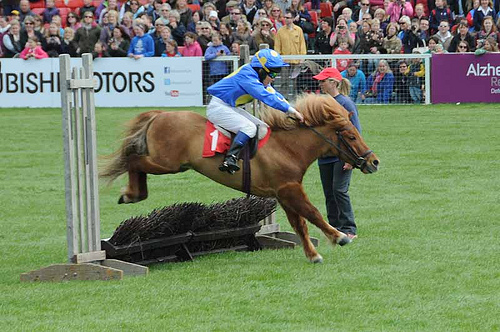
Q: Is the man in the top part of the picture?
A: Yes, the man is in the top of the image.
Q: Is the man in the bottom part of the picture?
A: No, the man is in the top of the image.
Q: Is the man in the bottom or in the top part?
A: The man is in the top of the image.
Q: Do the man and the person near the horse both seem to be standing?
A: Yes, both the man and the person are standing.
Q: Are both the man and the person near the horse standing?
A: Yes, both the man and the person are standing.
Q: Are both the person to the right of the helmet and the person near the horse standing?
A: Yes, both the man and the person are standing.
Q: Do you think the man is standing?
A: Yes, the man is standing.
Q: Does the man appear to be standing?
A: Yes, the man is standing.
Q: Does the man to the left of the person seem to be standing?
A: Yes, the man is standing.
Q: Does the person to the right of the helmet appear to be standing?
A: Yes, the man is standing.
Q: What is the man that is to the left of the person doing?
A: The man is standing.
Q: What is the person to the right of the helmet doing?
A: The man is standing.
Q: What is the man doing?
A: The man is standing.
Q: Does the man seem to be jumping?
A: No, the man is standing.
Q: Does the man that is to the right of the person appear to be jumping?
A: No, the man is standing.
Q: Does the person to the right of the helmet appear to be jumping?
A: No, the man is standing.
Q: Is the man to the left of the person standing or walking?
A: The man is standing.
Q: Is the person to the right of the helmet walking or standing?
A: The man is standing.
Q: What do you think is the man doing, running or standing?
A: The man is standing.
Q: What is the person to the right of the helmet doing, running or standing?
A: The man is standing.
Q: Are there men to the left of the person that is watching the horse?
A: Yes, there is a man to the left of the person.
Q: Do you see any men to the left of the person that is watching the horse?
A: Yes, there is a man to the left of the person.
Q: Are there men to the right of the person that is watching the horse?
A: No, the man is to the left of the person.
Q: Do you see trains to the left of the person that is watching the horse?
A: No, there is a man to the left of the person.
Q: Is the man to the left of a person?
A: Yes, the man is to the left of a person.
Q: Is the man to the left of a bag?
A: No, the man is to the left of a person.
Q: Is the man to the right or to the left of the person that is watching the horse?
A: The man is to the left of the person.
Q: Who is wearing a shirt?
A: The man is wearing a shirt.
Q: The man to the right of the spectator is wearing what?
A: The man is wearing a shirt.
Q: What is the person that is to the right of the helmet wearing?
A: The man is wearing a shirt.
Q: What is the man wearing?
A: The man is wearing a shirt.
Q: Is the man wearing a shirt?
A: Yes, the man is wearing a shirt.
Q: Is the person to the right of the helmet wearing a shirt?
A: Yes, the man is wearing a shirt.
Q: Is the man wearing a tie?
A: No, the man is wearing a shirt.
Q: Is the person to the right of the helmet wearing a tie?
A: No, the man is wearing a shirt.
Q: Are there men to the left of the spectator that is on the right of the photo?
A: Yes, there is a man to the left of the spectator.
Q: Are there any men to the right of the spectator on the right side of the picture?
A: No, the man is to the left of the spectator.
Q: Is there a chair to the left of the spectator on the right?
A: No, there is a man to the left of the spectator.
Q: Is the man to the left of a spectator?
A: Yes, the man is to the left of a spectator.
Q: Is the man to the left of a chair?
A: No, the man is to the left of a spectator.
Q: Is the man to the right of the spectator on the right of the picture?
A: No, the man is to the left of the spectator.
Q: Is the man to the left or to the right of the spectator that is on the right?
A: The man is to the left of the spectator.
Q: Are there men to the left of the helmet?
A: No, the man is to the right of the helmet.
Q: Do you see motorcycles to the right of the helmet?
A: No, there is a man to the right of the helmet.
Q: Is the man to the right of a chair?
A: No, the man is to the right of the helmet.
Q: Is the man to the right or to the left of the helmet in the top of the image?
A: The man is to the right of the helmet.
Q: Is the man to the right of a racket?
A: No, the man is to the right of a person.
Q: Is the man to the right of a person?
A: Yes, the man is to the right of a person.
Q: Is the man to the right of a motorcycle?
A: No, the man is to the right of a person.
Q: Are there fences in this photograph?
A: Yes, there is a fence.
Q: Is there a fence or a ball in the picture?
A: Yes, there is a fence.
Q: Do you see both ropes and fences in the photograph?
A: No, there is a fence but no ropes.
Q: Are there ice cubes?
A: No, there are no ice cubes.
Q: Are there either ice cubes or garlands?
A: No, there are no ice cubes or garlands.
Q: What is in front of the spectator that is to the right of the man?
A: The fence is in front of the spectator.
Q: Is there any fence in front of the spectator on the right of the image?
A: Yes, there is a fence in front of the spectator.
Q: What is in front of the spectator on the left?
A: The fence is in front of the spectator.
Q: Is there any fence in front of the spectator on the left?
A: Yes, there is a fence in front of the spectator.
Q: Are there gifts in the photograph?
A: No, there are no gifts.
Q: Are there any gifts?
A: No, there are no gifts.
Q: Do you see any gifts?
A: No, there are no gifts.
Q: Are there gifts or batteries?
A: No, there are no gifts or batteries.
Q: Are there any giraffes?
A: No, there are no giraffes.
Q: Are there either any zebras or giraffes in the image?
A: No, there are no giraffes or zebras.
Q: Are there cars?
A: No, there are no cars.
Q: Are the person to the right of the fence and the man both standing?
A: Yes, both the person and the man are standing.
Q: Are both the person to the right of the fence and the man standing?
A: Yes, both the person and the man are standing.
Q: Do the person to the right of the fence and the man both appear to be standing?
A: Yes, both the person and the man are standing.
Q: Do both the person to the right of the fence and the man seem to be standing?
A: Yes, both the person and the man are standing.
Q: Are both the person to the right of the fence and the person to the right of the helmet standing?
A: Yes, both the person and the man are standing.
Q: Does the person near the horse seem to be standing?
A: Yes, the person is standing.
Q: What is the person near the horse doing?
A: The person is standing.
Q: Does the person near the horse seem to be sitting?
A: No, the person is standing.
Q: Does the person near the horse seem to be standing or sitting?
A: The person is standing.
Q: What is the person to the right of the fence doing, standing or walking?
A: The person is standing.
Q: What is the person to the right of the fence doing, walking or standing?
A: The person is standing.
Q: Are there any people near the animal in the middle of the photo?
A: Yes, there is a person near the horse.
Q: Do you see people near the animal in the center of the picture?
A: Yes, there is a person near the horse.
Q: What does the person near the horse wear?
A: The person wears a hat.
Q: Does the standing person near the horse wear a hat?
A: Yes, the person wears a hat.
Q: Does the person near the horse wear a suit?
A: No, the person wears a hat.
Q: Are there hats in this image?
A: Yes, there is a hat.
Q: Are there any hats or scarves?
A: Yes, there is a hat.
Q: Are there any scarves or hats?
A: Yes, there is a hat.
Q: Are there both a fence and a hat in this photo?
A: Yes, there are both a hat and a fence.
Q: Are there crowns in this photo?
A: No, there are no crowns.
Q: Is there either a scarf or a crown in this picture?
A: No, there are no crowns or scarves.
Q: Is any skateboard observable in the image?
A: No, there are no skateboards.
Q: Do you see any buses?
A: No, there are no buses.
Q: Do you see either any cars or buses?
A: No, there are no buses or cars.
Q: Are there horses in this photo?
A: Yes, there is a horse.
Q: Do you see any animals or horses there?
A: Yes, there is a horse.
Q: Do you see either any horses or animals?
A: Yes, there is a horse.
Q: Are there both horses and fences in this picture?
A: Yes, there are both a horse and a fence.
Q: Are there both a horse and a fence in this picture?
A: Yes, there are both a horse and a fence.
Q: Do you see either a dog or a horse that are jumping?
A: Yes, the horse is jumping.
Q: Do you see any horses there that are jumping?
A: Yes, there is a horse that is jumping.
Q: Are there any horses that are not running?
A: Yes, there is a horse that is jumping.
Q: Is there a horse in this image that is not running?
A: Yes, there is a horse that is jumping.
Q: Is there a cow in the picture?
A: No, there are no cows.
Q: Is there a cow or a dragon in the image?
A: No, there are no cows or dragons.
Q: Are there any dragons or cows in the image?
A: No, there are no cows or dragons.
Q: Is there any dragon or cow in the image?
A: No, there are no cows or dragons.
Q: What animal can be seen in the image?
A: The animal is a horse.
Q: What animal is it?
A: The animal is a horse.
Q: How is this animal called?
A: This is a horse.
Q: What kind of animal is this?
A: This is a horse.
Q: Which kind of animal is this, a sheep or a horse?
A: This is a horse.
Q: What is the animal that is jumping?
A: The animal is a horse.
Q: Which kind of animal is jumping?
A: The animal is a horse.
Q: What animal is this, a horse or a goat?
A: This is a horse.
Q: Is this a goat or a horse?
A: This is a horse.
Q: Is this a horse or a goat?
A: This is a horse.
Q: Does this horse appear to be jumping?
A: Yes, the horse is jumping.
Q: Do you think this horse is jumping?
A: Yes, the horse is jumping.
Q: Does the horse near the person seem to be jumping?
A: Yes, the horse is jumping.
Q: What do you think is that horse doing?
A: The horse is jumping.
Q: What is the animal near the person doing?
A: The horse is jumping.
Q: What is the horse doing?
A: The horse is jumping.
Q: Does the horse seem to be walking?
A: No, the horse is jumping.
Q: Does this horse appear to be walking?
A: No, the horse is jumping.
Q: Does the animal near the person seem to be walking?
A: No, the horse is jumping.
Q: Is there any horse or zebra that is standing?
A: No, there is a horse but it is jumping.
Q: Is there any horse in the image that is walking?
A: No, there is a horse but it is jumping.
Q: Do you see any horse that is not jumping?
A: No, there is a horse but it is jumping.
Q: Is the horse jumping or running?
A: The horse is jumping.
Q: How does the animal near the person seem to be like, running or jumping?
A: The horse is jumping.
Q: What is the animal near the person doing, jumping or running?
A: The horse is jumping.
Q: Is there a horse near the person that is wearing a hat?
A: Yes, there is a horse near the person.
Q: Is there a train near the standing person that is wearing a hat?
A: No, there is a horse near the person.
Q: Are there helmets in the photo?
A: Yes, there is a helmet.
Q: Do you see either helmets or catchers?
A: Yes, there is a helmet.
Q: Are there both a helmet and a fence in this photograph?
A: Yes, there are both a helmet and a fence.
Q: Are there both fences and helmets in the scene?
A: Yes, there are both a helmet and a fence.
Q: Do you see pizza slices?
A: No, there are no pizza slices.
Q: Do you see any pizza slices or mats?
A: No, there are no pizza slices or mats.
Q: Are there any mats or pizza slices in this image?
A: No, there are no pizza slices or mats.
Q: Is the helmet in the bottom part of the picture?
A: No, the helmet is in the top of the image.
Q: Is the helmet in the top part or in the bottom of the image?
A: The helmet is in the top of the image.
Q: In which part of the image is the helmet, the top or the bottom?
A: The helmet is in the top of the image.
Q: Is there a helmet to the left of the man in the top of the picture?
A: Yes, there is a helmet to the left of the man.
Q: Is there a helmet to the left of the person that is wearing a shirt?
A: Yes, there is a helmet to the left of the man.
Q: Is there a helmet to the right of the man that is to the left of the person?
A: No, the helmet is to the left of the man.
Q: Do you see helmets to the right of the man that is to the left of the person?
A: No, the helmet is to the left of the man.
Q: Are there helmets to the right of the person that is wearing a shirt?
A: No, the helmet is to the left of the man.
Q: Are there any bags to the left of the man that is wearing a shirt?
A: No, there is a helmet to the left of the man.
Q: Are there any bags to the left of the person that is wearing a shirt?
A: No, there is a helmet to the left of the man.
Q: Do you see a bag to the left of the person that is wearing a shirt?
A: No, there is a helmet to the left of the man.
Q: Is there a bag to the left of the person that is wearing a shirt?
A: No, there is a helmet to the left of the man.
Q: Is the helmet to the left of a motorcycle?
A: No, the helmet is to the left of the man.